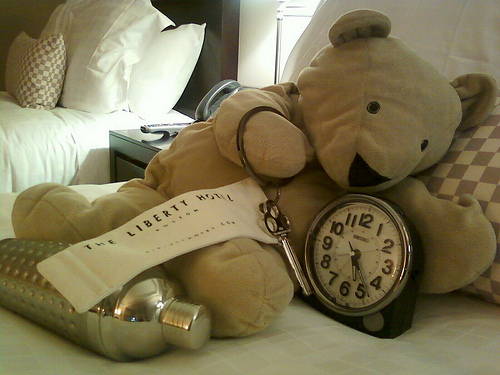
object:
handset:
[192, 77, 239, 121]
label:
[32, 173, 292, 315]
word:
[78, 235, 117, 255]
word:
[118, 197, 201, 237]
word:
[193, 188, 252, 204]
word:
[141, 241, 171, 256]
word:
[184, 220, 236, 239]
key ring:
[232, 99, 310, 207]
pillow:
[3, 30, 70, 110]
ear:
[448, 69, 497, 130]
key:
[252, 196, 318, 298]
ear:
[326, 6, 396, 49]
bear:
[5, 6, 499, 342]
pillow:
[133, 19, 210, 120]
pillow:
[47, 0, 181, 110]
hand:
[385, 179, 498, 296]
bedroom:
[0, 0, 499, 373]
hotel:
[191, 182, 236, 203]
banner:
[79, 191, 241, 251]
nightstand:
[103, 127, 250, 187]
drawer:
[114, 135, 176, 170]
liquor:
[0, 230, 223, 361]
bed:
[0, 0, 241, 196]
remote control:
[135, 113, 212, 139]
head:
[293, 6, 499, 196]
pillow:
[411, 91, 500, 308]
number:
[368, 272, 384, 292]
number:
[352, 280, 369, 300]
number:
[380, 259, 396, 276]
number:
[319, 233, 336, 251]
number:
[333, 221, 344, 236]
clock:
[291, 187, 427, 345]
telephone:
[189, 75, 258, 130]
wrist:
[209, 85, 312, 179]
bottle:
[0, 230, 216, 365]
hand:
[227, 102, 316, 185]